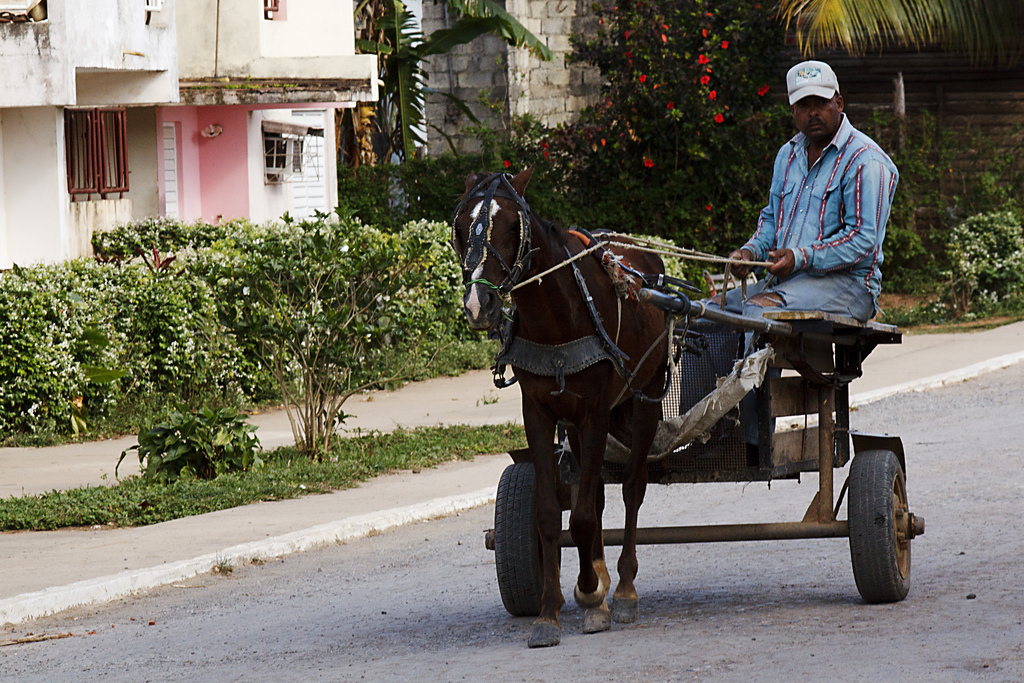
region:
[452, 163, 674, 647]
a chestnut colored horse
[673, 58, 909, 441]
a man in blue jeans and ball cap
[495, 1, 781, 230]
flowering foliage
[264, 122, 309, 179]
an air conditioning unit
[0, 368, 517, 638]
a concrete sidewalk path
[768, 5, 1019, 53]
a leaf of a palm tree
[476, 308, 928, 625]
a horse-drawn cart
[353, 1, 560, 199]
part of a banana tree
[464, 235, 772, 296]
the horse's reins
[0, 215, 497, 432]
a green hedge with white blooms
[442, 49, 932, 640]
man driving a pony cart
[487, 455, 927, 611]
wheels on pony cart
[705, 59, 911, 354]
man wearing worn blue jeans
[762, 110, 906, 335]
blue and pink striped button up shirt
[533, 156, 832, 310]
man's hands holding the reins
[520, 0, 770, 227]
lush flowering shrub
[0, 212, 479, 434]
trimmed hedges in front of a house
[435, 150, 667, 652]
pony pulling a cart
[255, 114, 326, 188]
air conditioner protruding from house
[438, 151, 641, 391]
harness around a pony's neck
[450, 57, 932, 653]
A man steering a horse-drawn carriage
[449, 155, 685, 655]
Small brown horse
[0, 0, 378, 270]
An old white building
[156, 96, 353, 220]
A pink entry way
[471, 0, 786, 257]
Vine with beautiful red flowers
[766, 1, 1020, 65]
Part of a palm leaf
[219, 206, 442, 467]
A small bush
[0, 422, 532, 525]
A patch of short grass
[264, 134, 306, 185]
A white air conditioner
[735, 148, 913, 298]
A pale blue and red stripped shirt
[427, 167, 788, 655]
Horse pulling a cart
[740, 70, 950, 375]
Man driving a cart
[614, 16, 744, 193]
Dark green leaves with red flowers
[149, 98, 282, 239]
Pink house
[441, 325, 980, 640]
Cart with two wheels with rubber tires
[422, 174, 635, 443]
Black horse with white facial markings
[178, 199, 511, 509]
Green shrub in the middle of the sidewalk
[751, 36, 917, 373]
Man with a white hat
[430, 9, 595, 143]
Grey brick wall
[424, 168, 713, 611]
A horse carrying a man in a carriage.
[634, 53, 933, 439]
A man riding a horse in a carriage.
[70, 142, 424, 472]
Green bushes beneath a house.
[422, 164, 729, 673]
A brown horse.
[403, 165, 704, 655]
A brown horse with silver hooves.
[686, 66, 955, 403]
A man with a hat and a blue shirt on.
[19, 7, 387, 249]
A white house with some pink on it.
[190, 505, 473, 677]
A street next to pavement.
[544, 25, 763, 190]
A tree with red on it.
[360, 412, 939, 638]
2 wheels on a carriage.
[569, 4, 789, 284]
A beautiful flowering bush.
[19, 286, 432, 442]
a shrub with white flowers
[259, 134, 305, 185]
air conditioning unit in window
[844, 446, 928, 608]
worn out cart tire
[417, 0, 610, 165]
stone exterior of building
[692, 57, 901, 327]
man holding horse reins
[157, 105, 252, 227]
exterior wall painted pink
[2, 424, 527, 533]
patch of lawn and weeds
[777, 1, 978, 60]
overhanging palm tree fronds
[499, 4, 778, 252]
dark green bush with red flowers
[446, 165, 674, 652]
horse pulling cart